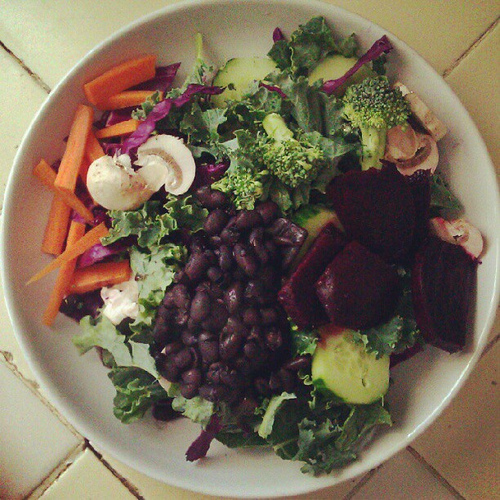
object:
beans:
[188, 291, 212, 325]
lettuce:
[178, 30, 213, 93]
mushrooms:
[135, 134, 196, 195]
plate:
[0, 0, 499, 498]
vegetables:
[389, 79, 451, 145]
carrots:
[76, 51, 156, 105]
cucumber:
[308, 321, 389, 406]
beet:
[154, 99, 171, 118]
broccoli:
[258, 112, 327, 189]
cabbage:
[375, 313, 415, 348]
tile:
[0, 41, 51, 216]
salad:
[64, 110, 365, 267]